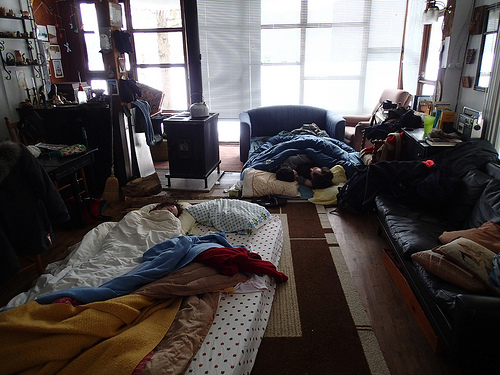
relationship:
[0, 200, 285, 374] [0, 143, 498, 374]
mattress on floor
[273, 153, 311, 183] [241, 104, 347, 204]
person on pull out chair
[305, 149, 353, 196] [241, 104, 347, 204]
person on pull out chair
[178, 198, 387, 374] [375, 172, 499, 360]
rug in front of couch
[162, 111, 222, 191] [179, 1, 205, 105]
stove has smoke pipe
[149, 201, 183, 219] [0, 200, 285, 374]
person laying on mattress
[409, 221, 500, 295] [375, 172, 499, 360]
pillows on couch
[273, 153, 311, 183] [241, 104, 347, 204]
person laying on pull out chair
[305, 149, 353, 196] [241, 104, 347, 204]
person laying on pull out chair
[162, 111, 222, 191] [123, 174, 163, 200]
stove burns wood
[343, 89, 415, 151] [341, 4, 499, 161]
chair in corner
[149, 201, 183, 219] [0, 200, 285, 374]
person on mattress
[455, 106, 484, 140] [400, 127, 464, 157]
radio on desk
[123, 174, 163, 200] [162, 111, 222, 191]
wood for stove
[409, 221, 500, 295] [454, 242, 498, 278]
pillows have ducks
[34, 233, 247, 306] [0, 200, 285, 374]
blanket on mattress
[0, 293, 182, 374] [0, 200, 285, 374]
blanket on mattress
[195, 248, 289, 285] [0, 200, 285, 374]
blanket on mattress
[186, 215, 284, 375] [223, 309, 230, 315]
sheet has print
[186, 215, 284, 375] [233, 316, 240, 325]
sheet has print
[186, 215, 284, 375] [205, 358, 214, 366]
sheet has print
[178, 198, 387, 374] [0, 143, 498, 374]
rug on floor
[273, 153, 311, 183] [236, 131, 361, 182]
person under blanket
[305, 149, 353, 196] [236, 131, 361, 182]
person under blanket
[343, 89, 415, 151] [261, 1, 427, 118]
chair near windows